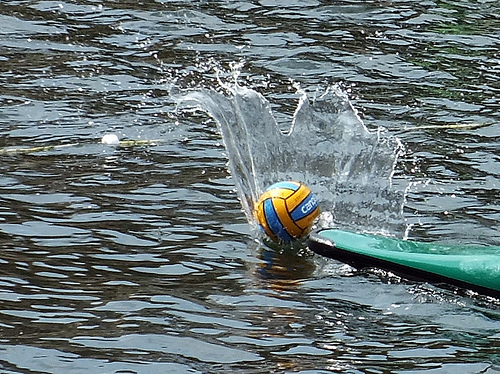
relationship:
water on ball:
[3, 6, 490, 372] [248, 178, 321, 240]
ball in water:
[253, 181, 318, 246] [3, 6, 490, 372]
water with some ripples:
[3, 6, 490, 372] [80, 191, 187, 238]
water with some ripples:
[3, 6, 490, 372] [0, 0, 499, 373]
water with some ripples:
[0, 0, 500, 373] [92, 249, 251, 365]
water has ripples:
[3, 6, 490, 372] [7, 321, 80, 368]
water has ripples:
[3, 6, 490, 372] [419, 82, 488, 136]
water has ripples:
[3, 6, 490, 372] [35, 85, 98, 195]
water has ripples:
[3, 6, 490, 372] [9, 3, 110, 59]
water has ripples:
[3, 6, 490, 372] [160, 222, 229, 335]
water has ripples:
[0, 0, 500, 373] [17, 279, 99, 306]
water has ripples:
[3, 6, 490, 372] [0, 0, 499, 373]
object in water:
[306, 212, 497, 298] [76, 153, 178, 308]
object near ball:
[306, 226, 499, 292] [247, 176, 329, 246]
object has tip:
[306, 226, 499, 292] [292, 203, 359, 274]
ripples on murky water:
[0, 0, 500, 372] [7, 3, 495, 372]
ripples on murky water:
[0, 0, 500, 372] [17, 129, 207, 366]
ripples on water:
[0, 0, 500, 372] [3, 6, 490, 372]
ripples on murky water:
[114, 293, 359, 368] [224, 301, 297, 346]